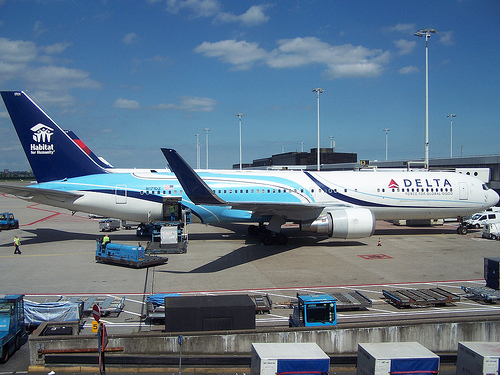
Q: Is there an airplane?
A: Yes, there is an airplane.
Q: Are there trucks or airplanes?
A: Yes, there is an airplane.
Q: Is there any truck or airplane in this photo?
A: Yes, there is an airplane.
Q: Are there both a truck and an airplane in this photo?
A: Yes, there are both an airplane and a truck.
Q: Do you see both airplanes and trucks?
A: Yes, there are both an airplane and a truck.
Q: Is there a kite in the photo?
A: No, there are no kites.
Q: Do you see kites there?
A: No, there are no kites.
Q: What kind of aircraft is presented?
A: The aircraft is an airplane.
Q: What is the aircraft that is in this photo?
A: The aircraft is an airplane.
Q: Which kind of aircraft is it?
A: The aircraft is an airplane.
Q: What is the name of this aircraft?
A: This is an airplane.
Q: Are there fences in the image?
A: No, there are no fences.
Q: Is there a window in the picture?
A: Yes, there are windows.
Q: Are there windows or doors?
A: Yes, there are windows.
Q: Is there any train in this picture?
A: No, there are no trains.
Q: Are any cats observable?
A: No, there are no cats.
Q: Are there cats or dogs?
A: No, there are no cats or dogs.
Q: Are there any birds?
A: No, there are no birds.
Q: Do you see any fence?
A: No, there are no fences.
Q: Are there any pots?
A: No, there are no pots.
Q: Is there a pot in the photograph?
A: No, there are no pots.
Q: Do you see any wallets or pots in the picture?
A: No, there are no pots or wallets.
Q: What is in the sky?
A: The clouds are in the sky.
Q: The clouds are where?
A: The clouds are in the sky.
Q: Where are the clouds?
A: The clouds are in the sky.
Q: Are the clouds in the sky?
A: Yes, the clouds are in the sky.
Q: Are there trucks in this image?
A: Yes, there is a truck.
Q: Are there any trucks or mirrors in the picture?
A: Yes, there is a truck.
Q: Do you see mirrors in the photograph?
A: No, there are no mirrors.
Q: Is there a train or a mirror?
A: No, there are no mirrors or trains.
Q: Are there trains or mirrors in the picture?
A: No, there are no mirrors or trains.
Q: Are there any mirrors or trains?
A: No, there are no mirrors or trains.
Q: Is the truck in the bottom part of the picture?
A: Yes, the truck is in the bottom of the image.